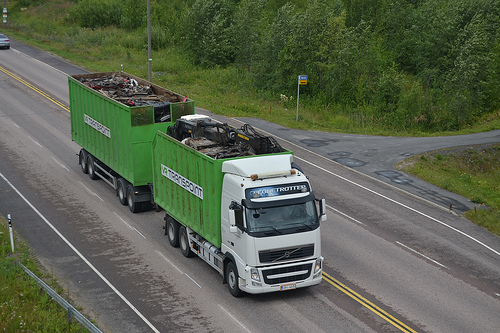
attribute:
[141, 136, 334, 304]
truck — travelling, pulling, carrying, green, white, hauling, halling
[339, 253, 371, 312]
lines — white, yellow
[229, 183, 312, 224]
cab — white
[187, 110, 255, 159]
pile — metal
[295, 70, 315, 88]
sign — white